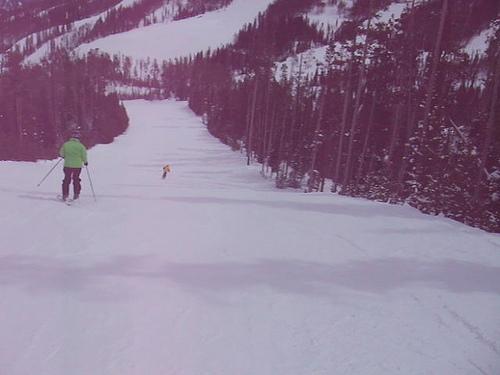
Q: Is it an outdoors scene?
A: Yes, it is outdoors.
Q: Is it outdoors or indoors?
A: It is outdoors.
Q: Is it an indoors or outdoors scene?
A: It is outdoors.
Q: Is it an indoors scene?
A: No, it is outdoors.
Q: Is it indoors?
A: No, it is outdoors.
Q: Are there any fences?
A: No, there are no fences.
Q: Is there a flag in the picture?
A: No, there are no flags.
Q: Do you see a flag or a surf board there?
A: No, there are no flags or surfboards.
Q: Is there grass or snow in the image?
A: Yes, there is snow.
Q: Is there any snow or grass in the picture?
A: Yes, there is snow.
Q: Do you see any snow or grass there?
A: Yes, there is snow.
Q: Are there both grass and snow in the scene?
A: No, there is snow but no grass.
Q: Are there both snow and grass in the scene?
A: No, there is snow but no grass.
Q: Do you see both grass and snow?
A: No, there is snow but no grass.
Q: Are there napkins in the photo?
A: No, there are no napkins.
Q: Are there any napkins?
A: No, there are no napkins.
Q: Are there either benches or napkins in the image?
A: No, there are no napkins or benches.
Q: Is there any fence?
A: No, there are no fences.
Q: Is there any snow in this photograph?
A: Yes, there is snow.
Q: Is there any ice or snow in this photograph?
A: Yes, there is snow.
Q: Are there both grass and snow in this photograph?
A: No, there is snow but no grass.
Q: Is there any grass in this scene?
A: No, there is no grass.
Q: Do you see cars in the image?
A: No, there are no cars.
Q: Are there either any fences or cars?
A: No, there are no cars or fences.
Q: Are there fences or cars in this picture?
A: No, there are no fences or cars.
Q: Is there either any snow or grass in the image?
A: Yes, there is snow.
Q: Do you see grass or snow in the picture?
A: Yes, there is snow.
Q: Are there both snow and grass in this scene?
A: No, there is snow but no grass.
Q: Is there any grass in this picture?
A: No, there is no grass.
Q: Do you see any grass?
A: No, there is no grass.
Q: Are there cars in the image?
A: No, there are no cars.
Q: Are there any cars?
A: No, there are no cars.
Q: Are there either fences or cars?
A: No, there are no cars or fences.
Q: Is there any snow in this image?
A: Yes, there is snow.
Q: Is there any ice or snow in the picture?
A: Yes, there is snow.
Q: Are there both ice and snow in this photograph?
A: No, there is snow but no ice.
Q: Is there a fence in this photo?
A: No, there are no fences.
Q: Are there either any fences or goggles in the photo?
A: No, there are no fences or goggles.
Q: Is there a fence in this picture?
A: No, there are no fences.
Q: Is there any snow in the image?
A: Yes, there is snow.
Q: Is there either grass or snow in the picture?
A: Yes, there is snow.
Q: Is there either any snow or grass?
A: Yes, there is snow.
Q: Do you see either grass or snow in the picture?
A: Yes, there is snow.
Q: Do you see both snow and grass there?
A: No, there is snow but no grass.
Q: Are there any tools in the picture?
A: No, there are no tools.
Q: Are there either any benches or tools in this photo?
A: No, there are no tools or benches.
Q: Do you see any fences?
A: No, there are no fences.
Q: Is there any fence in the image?
A: No, there are no fences.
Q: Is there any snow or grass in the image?
A: Yes, there is snow.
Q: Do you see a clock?
A: No, there are no clocks.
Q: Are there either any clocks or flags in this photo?
A: No, there are no clocks or flags.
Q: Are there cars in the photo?
A: No, there are no cars.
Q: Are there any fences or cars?
A: No, there are no cars or fences.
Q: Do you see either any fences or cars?
A: No, there are no cars or fences.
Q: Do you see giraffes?
A: No, there are no giraffes.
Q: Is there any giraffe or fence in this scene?
A: No, there are no giraffes or fences.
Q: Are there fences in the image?
A: No, there are no fences.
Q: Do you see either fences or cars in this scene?
A: No, there are no fences or cars.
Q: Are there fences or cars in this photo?
A: No, there are no cars or fences.